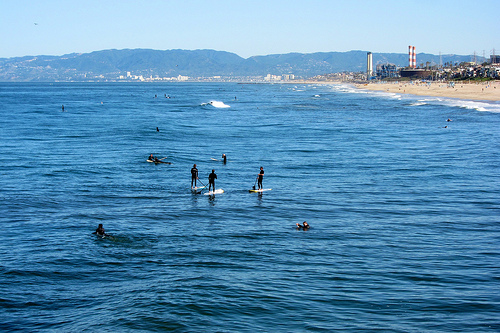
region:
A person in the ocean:
[247, 157, 276, 196]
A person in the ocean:
[287, 214, 337, 244]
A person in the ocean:
[206, 164, 226, 199]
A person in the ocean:
[77, 215, 125, 247]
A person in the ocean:
[180, 146, 201, 188]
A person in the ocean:
[147, 139, 174, 185]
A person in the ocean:
[58, 96, 79, 122]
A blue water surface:
[335, 199, 499, 319]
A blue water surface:
[140, 244, 282, 321]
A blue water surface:
[44, 69, 386, 164]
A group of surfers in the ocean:
[77, 143, 324, 253]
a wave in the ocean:
[204, 96, 230, 109]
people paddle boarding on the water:
[186, 160, 274, 200]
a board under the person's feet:
[248, 185, 272, 193]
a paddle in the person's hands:
[250, 171, 260, 190]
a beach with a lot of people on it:
[358, 78, 498, 106]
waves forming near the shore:
[336, 83, 498, 120]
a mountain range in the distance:
[1, 43, 491, 79]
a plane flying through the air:
[32, 16, 38, 27]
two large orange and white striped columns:
[407, 43, 417, 67]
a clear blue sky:
[0, 0, 499, 57]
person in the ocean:
[92, 222, 110, 236]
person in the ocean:
[190, 164, 199, 189]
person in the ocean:
[208, 169, 219, 193]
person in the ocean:
[256, 165, 271, 190]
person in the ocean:
[221, 152, 228, 162]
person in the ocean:
[170, 125, 176, 134]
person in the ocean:
[295, 221, 313, 231]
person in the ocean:
[145, 152, 150, 160]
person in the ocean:
[155, 125, 165, 131]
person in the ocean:
[60, 105, 69, 112]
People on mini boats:
[170, 148, 304, 221]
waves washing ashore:
[364, 81, 458, 123]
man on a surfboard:
[248, 163, 276, 205]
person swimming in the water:
[84, 211, 122, 251]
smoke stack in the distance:
[405, 44, 420, 74]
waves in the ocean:
[198, 97, 232, 113]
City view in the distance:
[117, 72, 314, 86]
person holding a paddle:
[188, 180, 212, 197]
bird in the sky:
[48, 98, 111, 130]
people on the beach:
[391, 69, 459, 96]